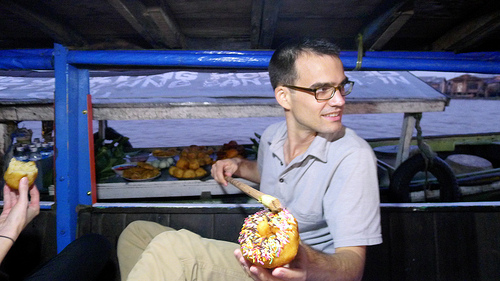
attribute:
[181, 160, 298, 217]
stick — long, wooden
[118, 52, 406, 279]
person — sitting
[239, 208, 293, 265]
sprinkles — multi colored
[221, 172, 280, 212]
stick — wooden, long, circular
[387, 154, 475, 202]
tire — black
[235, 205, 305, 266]
donut — large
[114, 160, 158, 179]
tray — full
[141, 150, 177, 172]
tray — full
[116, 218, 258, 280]
pants — long